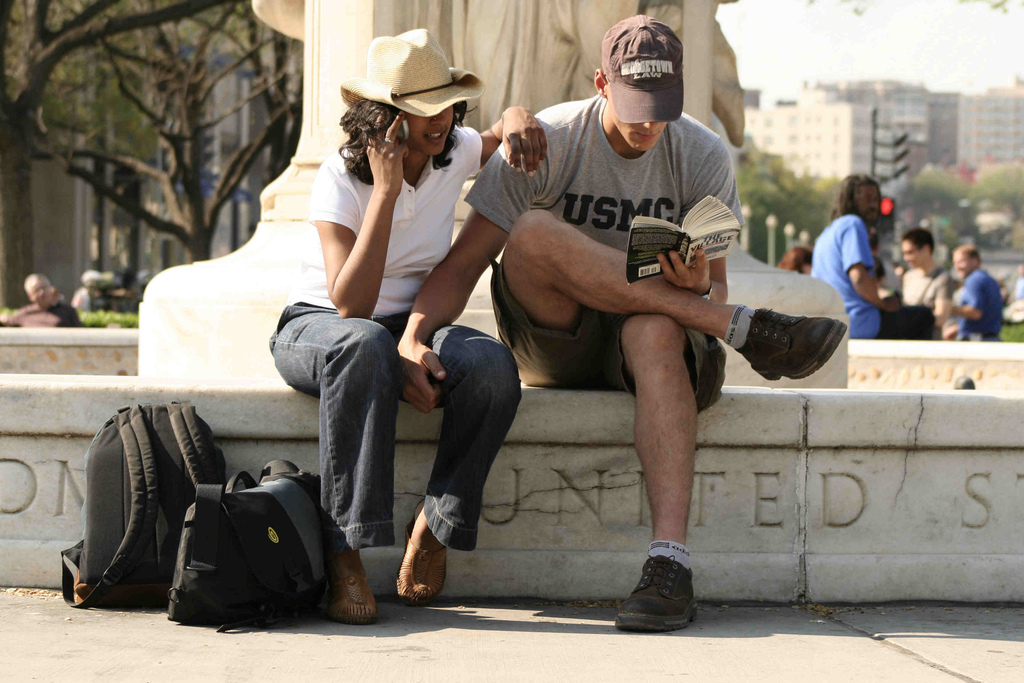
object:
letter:
[549, 467, 612, 528]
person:
[862, 211, 894, 274]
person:
[775, 229, 816, 279]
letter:
[736, 444, 801, 538]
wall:
[0, 398, 1011, 603]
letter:
[803, 454, 871, 537]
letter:
[948, 448, 1006, 557]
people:
[264, 8, 848, 638]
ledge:
[0, 370, 1024, 451]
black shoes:
[611, 547, 699, 636]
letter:
[548, 446, 606, 542]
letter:
[814, 456, 868, 545]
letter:
[945, 459, 992, 540]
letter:
[544, 458, 616, 532]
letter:
[747, 459, 794, 537]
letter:
[749, 467, 786, 532]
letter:
[818, 463, 868, 531]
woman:
[259, 24, 552, 627]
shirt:
[307, 122, 484, 323]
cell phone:
[383, 109, 414, 149]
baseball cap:
[595, 3, 691, 126]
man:
[389, 10, 862, 640]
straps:
[71, 403, 162, 608]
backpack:
[58, 397, 233, 609]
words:
[952, 467, 1005, 533]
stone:
[5, 374, 1024, 603]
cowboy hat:
[337, 23, 489, 120]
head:
[340, 79, 471, 171]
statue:
[135, 0, 850, 385]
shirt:
[465, 90, 742, 276]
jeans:
[265, 298, 404, 553]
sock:
[643, 537, 695, 574]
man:
[807, 168, 936, 348]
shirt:
[807, 213, 886, 339]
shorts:
[605, 307, 728, 419]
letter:
[633, 467, 666, 528]